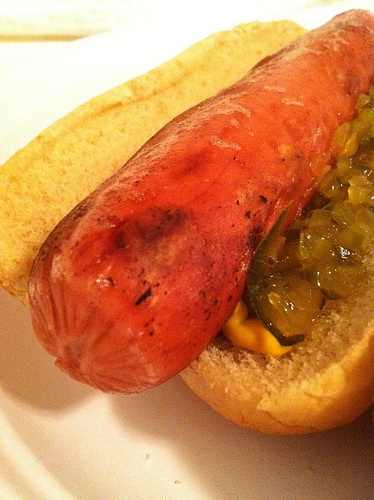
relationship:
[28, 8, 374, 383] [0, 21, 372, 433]
cooked hotdog on bun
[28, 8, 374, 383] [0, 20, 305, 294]
cooked hotdog in bun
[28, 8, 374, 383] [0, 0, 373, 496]
cooked hotdog on plate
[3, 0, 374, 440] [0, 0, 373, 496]
bun on plate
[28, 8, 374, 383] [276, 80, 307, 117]
cooked hotdog has bubble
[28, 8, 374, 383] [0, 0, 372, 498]
cooked hotdog on table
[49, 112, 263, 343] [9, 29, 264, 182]
cooked hotdog on a bun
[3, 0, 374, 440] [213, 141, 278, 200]
bun with hotdog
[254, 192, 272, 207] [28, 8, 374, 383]
spot on a cooked hotdog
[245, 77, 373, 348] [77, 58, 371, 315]
relish on hotdog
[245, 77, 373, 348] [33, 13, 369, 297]
relish on hot dog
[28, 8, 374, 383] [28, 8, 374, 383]
cooked hotdog has cooked hotdog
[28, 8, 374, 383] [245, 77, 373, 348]
cooked hotdog with relish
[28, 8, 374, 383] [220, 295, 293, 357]
cooked hotdog with mustard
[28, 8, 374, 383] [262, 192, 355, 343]
cooked hotdog with relish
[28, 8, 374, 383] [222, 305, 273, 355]
cooked hotdog with mustard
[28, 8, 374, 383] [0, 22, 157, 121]
cooked hotdog on a plate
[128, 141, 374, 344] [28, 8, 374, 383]
spot on cooked hotdog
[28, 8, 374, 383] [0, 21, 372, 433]
cooked hotdog on a bun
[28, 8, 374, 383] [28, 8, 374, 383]
cooked hotdog of cooked hotdog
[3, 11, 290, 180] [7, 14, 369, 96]
bun on plate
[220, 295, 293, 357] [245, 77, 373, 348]
mustard underneath relish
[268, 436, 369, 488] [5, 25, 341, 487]
crumb on plate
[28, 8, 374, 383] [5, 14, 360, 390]
cooked hotdog on table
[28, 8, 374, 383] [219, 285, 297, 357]
cooked hotdog with mustard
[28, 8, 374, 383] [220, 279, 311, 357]
cooked hotdog with mustard